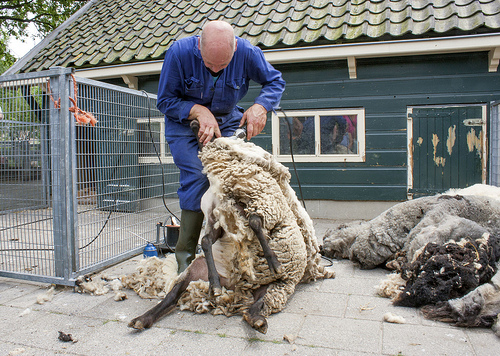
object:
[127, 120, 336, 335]
sheep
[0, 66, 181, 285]
fence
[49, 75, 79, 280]
metal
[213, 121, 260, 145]
shearer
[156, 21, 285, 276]
man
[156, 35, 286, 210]
suit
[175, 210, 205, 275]
boots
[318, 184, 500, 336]
sheep wool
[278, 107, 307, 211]
cord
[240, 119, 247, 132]
tool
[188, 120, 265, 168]
head